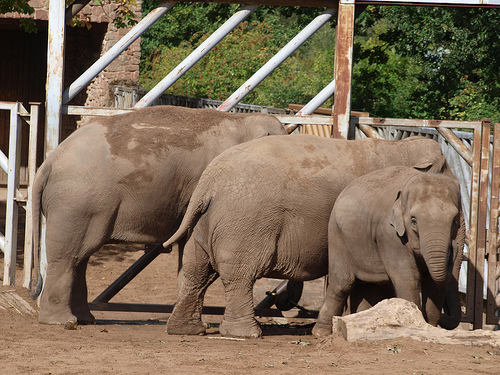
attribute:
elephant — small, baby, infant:
[321, 161, 482, 342]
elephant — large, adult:
[21, 105, 318, 323]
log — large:
[314, 304, 495, 360]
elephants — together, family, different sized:
[25, 127, 486, 332]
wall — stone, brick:
[7, 7, 141, 121]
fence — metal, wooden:
[1, 109, 56, 299]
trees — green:
[146, 5, 488, 111]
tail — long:
[23, 171, 60, 299]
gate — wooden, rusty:
[453, 125, 492, 303]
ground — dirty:
[13, 323, 352, 370]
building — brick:
[2, 2, 147, 105]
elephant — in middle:
[165, 135, 438, 310]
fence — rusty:
[322, 4, 367, 112]